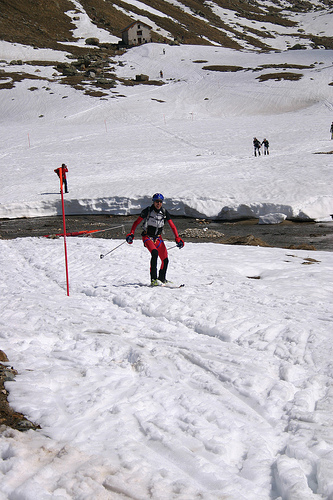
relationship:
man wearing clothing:
[125, 193, 184, 286] [125, 204, 184, 280]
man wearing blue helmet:
[125, 193, 184, 286] [151, 192, 165, 200]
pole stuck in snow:
[57, 169, 72, 295] [1, 1, 321, 498]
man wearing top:
[125, 193, 184, 286] [138, 203, 172, 238]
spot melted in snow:
[245, 274, 260, 280] [1, 1, 321, 498]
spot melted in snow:
[283, 258, 291, 262] [1, 1, 321, 498]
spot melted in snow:
[285, 253, 295, 257] [1, 1, 321, 498]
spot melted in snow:
[301, 260, 313, 266] [1, 1, 321, 498]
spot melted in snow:
[302, 257, 321, 263] [1, 1, 321, 498]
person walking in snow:
[252, 136, 261, 154] [1, 1, 321, 498]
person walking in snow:
[259, 136, 270, 154] [1, 1, 321, 498]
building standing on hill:
[118, 19, 153, 48] [1, 1, 321, 121]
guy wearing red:
[54, 162, 69, 192] [53, 165, 68, 177]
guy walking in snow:
[54, 162, 69, 192] [1, 1, 321, 498]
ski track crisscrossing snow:
[83, 327, 126, 337] [4, 234, 327, 492]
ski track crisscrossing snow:
[174, 348, 276, 426] [4, 234, 327, 492]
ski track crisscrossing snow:
[121, 414, 225, 490] [4, 234, 327, 492]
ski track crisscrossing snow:
[1, 381, 140, 495] [4, 234, 327, 492]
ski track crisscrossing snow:
[138, 334, 208, 345] [4, 234, 327, 492]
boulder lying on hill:
[57, 61, 70, 69] [1, 1, 321, 121]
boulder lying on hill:
[88, 69, 96, 78] [1, 1, 321, 121]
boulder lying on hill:
[66, 53, 83, 59] [1, 1, 321, 121]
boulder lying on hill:
[84, 36, 100, 45] [1, 1, 321, 121]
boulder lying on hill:
[101, 59, 110, 67] [1, 1, 321, 121]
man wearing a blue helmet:
[125, 193, 184, 286] [150, 190, 165, 202]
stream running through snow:
[14, 213, 299, 245] [94, 298, 322, 465]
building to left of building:
[122, 20, 153, 49] [122, 20, 153, 49]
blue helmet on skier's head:
[150, 191, 165, 201] [150, 191, 164, 209]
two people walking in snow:
[249, 135, 270, 158] [136, 122, 228, 172]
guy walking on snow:
[54, 162, 69, 192] [86, 147, 188, 190]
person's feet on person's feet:
[150, 279, 165, 287] [146, 277, 172, 284]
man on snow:
[125, 193, 184, 286] [34, 250, 270, 412]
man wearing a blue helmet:
[125, 193, 184, 286] [150, 191, 165, 201]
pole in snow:
[55, 165, 73, 295] [4, 234, 327, 492]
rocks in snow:
[3, 352, 42, 430] [4, 234, 327, 492]